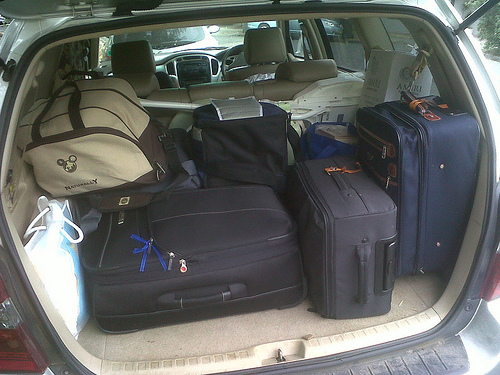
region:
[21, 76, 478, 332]
luggage in the car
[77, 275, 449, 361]
the floor is beige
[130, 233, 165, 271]
the ribbon is blue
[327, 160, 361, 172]
the ribbon is orange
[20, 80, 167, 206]
the duffle bag is brown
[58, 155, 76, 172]
a mickey mouse logo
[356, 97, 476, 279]
the suit case is blue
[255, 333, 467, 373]
the rubber is black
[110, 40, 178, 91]
driver seat of car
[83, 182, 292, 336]
this is a briefcase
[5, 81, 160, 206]
this is a bag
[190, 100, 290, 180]
this is a bag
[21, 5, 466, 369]
this is a car`s boot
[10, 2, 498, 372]
this is a car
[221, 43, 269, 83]
this is a steering wheel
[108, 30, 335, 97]
these are chairs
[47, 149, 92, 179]
design on back of brown backpack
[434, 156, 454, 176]
silver metal rivet on luggage side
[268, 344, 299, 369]
rear door latch on vehicle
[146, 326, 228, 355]
carpet on floor in vehicle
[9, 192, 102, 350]
white bag sitting in car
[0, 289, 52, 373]
red tail light on vehicle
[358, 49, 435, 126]
white cardboard box in car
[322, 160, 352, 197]
black handle on suitcase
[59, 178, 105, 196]
text on brown backpack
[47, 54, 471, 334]
luggage in back of vehicle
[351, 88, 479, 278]
piece of luggage in van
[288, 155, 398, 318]
piece of luggage in van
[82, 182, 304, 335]
piece of luggage in van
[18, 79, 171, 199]
piece of luggage in van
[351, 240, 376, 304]
handle on a suitcase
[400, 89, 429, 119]
handle on a suitcase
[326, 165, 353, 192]
handle on a suitcase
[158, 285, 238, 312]
handle on a suitcase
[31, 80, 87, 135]
handle on a suitcase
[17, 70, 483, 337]
A mini vans cargo area packed with traveling suit cases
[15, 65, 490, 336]
A mini vans cargo area packed with traveling suit cases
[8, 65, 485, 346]
A mini vans cargo area packed with traveling suit cases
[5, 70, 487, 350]
A mini vans cargo area packed with traveling suit cases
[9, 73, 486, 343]
A mini vans cargo area packed with traveling suit cases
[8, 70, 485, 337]
A mini vans cargo area packed with traveling suit cases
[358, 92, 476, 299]
Blue suitcase in trunk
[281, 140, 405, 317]
Black suitcase in trunk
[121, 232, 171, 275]
A blue tag on the zipper.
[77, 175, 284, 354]
A black luggage in the back of the car.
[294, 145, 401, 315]
Black luggage in the back of the car.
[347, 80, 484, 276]
Blue luggage in the back of the car.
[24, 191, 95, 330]
A white bag next to the luggage.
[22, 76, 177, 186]
A brown and tan luggage in the back of the car.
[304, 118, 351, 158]
A blue bag next to the luggage.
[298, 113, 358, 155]
A blue bag next to the luggage.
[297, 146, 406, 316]
a piece of black luggage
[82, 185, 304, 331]
a piece of black luggage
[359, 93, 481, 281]
a piece of black luggage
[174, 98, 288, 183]
a piece of black luggage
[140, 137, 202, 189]
a piece of black luggage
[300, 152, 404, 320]
a piece of black luggage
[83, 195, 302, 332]
a piece of black luggage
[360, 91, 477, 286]
a piece of black luggage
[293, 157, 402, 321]
a piece of black luggage